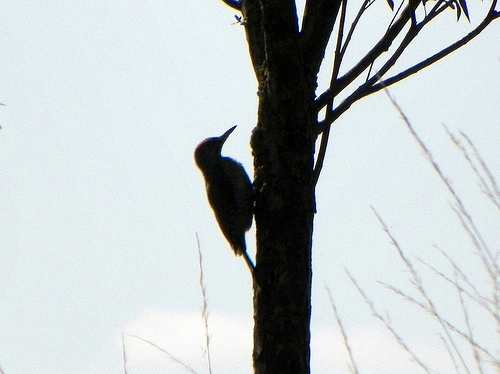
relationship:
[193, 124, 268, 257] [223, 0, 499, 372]
bird on tree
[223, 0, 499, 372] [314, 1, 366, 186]
tree has stem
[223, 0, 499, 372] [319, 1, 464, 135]
tree has branch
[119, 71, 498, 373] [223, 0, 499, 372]
grass with tree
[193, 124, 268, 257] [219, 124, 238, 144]
bird has beak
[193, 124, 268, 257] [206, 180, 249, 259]
bird has wings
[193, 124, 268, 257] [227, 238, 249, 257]
bird has tail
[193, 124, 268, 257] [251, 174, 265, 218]
bird has feet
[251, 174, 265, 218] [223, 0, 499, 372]
feet holding into tree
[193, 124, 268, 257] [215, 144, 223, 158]
bird has eye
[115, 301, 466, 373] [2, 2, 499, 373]
clouds in sky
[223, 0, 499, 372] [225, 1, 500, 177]
tree has branches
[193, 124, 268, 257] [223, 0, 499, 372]
bird hanging on tree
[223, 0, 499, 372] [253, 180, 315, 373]
tree has trunk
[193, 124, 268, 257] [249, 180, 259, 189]
bird has leg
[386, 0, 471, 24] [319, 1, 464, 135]
leaves on branch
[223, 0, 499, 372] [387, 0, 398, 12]
tree has leaf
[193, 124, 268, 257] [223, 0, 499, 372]
bird holding onto tree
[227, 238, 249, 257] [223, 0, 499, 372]
tail against tree